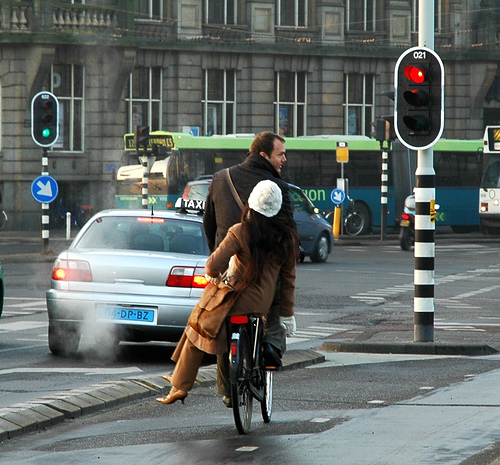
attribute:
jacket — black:
[206, 165, 279, 231]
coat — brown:
[217, 220, 286, 329]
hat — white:
[243, 179, 284, 224]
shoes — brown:
[152, 369, 192, 402]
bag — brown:
[193, 283, 236, 332]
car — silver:
[57, 193, 210, 351]